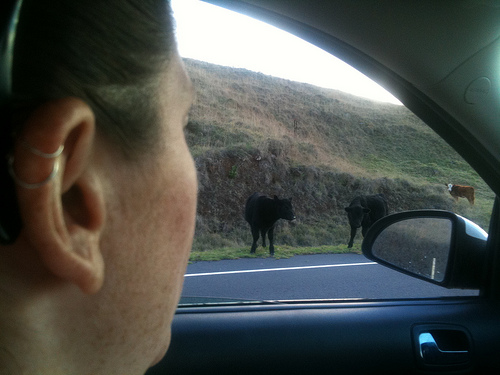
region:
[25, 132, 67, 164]
The top hoop earring in the girl's ear.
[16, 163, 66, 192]
The bottom loop earring in the girl's ear.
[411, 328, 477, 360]
The silver door handle.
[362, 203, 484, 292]
The side mirror on the car.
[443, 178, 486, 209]
The brown and white cow standing in the grass.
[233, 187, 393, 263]
The two black cows near the street.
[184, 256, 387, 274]
The white line in the street.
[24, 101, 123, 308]
The ear of the girl looking at the cows.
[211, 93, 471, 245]
The grassy hill behind the cows.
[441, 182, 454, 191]
The white head of the brown cow.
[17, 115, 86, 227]
two earring on woman's ear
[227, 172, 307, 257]
the cow is black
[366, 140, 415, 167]
the grass is green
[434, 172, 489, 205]
the cow is brown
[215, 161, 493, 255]
three cows on the sidewalk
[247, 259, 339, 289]
the line is white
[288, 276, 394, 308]
the road is gray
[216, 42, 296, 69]
the sky is white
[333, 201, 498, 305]
the side mirror is black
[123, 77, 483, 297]
woman is watching the cows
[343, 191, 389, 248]
black cow looking at car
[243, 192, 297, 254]
black cow looking at other black cow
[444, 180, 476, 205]
red cow with white face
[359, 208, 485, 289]
driver side rear view mirror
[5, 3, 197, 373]
person looking at cows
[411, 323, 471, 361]
silver door handle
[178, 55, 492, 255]
hills with dead grass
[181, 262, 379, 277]
white line on road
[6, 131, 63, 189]
silver hoop earrings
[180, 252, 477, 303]
road in front of the cows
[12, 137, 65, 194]
TWO PIERCED HOOP EARRINGS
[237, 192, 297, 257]
BLACK ANGUS YOUNG COW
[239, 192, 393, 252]
TWO YOUNG BLACK ANGUS COWS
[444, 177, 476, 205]
HERFORD COW IN PASTURE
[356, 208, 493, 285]
DRIVERS SIDE, SIDE MIRROR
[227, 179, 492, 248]
THREE COWS IN A FIELD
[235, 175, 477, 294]
THREE COWS NEAR SIDE OF ROAD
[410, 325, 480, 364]
DRIVERS SIDE INTERIOR DOOR HANDLE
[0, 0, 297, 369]
WOMAN LOOKING AT COW NEAR ROAD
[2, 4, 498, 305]
WOMAN LOOKING AT COWS FROM INSIDE A CAR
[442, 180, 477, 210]
a brown and white cow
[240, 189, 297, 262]
a black cow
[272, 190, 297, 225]
the head of a black cow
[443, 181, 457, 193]
the head of a brown and white cow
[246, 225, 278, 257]
the legs of a black cow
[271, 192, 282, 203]
the ear of a black cow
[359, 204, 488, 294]
a side view mirror on a car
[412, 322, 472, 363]
the inner door handle of a car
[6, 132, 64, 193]
two metal earrings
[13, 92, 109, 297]
the ear of a person